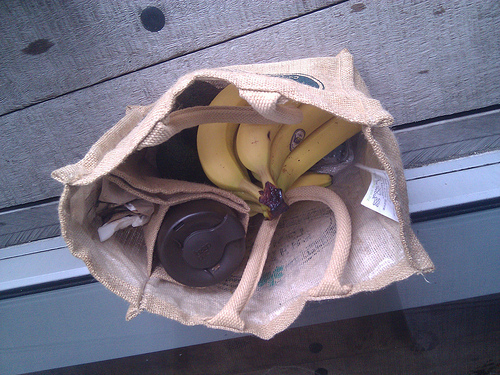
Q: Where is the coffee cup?
A: In the bag.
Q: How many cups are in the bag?
A: One.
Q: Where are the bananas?
A: In the bag.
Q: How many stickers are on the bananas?
A: One.